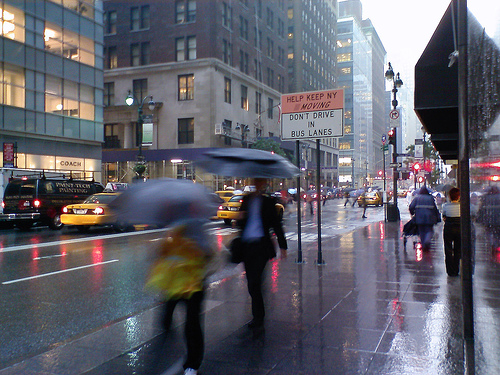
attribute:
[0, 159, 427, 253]
traffic — slowed, stopped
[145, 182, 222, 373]
person — blurr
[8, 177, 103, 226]
van — black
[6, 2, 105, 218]
left buildings — tall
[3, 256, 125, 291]
line — white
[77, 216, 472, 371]
sidewalk — wet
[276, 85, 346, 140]
sign — orange, white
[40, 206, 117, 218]
lights — brake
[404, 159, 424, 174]
light — red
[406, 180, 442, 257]
person — walking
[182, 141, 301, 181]
umbrella — black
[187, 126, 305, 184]
umbrella — open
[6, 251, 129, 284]
lines — white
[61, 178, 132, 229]
car — yellow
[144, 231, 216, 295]
raincoat — yellow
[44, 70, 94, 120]
window — wide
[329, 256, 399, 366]
sidewalk — wet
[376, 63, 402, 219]
light — tall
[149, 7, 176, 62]
wall — brown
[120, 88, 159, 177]
street light — on, off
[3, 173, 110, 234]
van — green